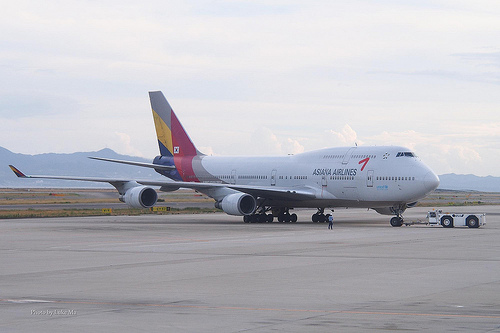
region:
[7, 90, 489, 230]
Asiana airlines jet airliner being pushed away from gate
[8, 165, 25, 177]
winglet on end of wing for fuel efficiency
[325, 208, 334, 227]
airport ramp staff person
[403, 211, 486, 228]
small tractor tug for pushing aircraft back from gate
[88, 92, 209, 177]
tail of aircraft with vertical and horizontal stabilizers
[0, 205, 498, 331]
expanse of gray airport tarmac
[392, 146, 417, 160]
cockpit area on large jumbo jet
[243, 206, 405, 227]
jumbo jet landing gears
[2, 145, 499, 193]
hazy purple mountains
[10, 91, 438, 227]
multi-engine jumbo jet aircraft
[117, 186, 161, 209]
Jet engine on airplane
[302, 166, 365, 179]
Airplane business owner name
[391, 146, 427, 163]
cockpit of passenger airplane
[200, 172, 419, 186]
Passenger windows on airplane fuselage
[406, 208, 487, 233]
Airport airplane guide cart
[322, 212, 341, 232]
man standing on airport runway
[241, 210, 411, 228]
Landing gear of airplane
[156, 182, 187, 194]
Flaps mechanism housing unit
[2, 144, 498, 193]
Mountains in distant background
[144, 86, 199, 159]
Tail of passenger jet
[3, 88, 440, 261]
a plane on the ground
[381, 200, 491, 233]
a truck towing a plane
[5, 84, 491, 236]
a large plane on the tarmack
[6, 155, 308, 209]
the wing on a plane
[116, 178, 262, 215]
engines on a plane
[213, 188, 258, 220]
an engine on a plane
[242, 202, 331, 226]
wheels on a plane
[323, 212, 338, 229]
a person standing on a plane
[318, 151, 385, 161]
windows on an airplane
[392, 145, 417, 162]
windshield on an airplane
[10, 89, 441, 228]
A large red, yellow, blue, and white airplane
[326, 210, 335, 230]
a person on a runway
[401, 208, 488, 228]
A white Pushback truck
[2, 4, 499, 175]
A cloudy sky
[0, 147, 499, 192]
some mountains in the distance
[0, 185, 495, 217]
some grassy fields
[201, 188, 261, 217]
the right wing engine of a plane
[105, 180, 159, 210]
the right wing engine of a plane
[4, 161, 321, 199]
the right wing of a plane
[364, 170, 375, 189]
a door on a plane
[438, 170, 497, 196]
hazy mountains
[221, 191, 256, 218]
a single plane engine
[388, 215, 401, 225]
a black front wheel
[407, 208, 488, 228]
a airport towing cart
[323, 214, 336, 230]
a man standing on a tarmac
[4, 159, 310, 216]
an airplane wing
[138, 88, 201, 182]
the tail of a plane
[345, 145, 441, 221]
the front of the plane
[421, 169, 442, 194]
the nose of a plane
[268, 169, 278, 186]
an emergancy door